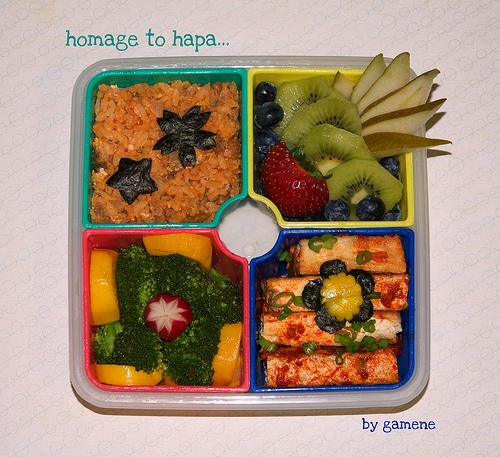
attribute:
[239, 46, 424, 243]
container — yellow 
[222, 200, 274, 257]
sauce — dipping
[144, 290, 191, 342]
radish — red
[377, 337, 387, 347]
onions — Green , sprinkled 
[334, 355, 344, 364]
onions — Green , sprinkled 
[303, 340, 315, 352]
onions — Green , sprinkled 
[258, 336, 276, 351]
onions — Green , sprinkled 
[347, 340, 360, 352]
onions — Green , sprinkled 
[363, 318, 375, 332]
onions — Green , sprinkled 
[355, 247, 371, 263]
onions — Green , sprinkled 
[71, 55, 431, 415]
container — yellow 